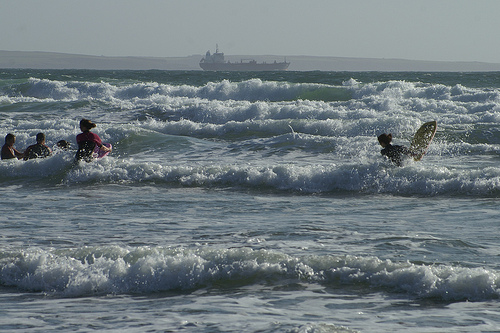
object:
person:
[377, 132, 412, 165]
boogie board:
[406, 121, 436, 162]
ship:
[198, 44, 290, 71]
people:
[0, 133, 26, 159]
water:
[0, 76, 499, 332]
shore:
[0, 48, 500, 79]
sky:
[0, 1, 499, 64]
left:
[0, 3, 27, 329]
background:
[0, 0, 500, 332]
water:
[0, 68, 499, 86]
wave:
[0, 243, 499, 301]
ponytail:
[383, 134, 395, 140]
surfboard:
[96, 142, 113, 159]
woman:
[73, 118, 113, 163]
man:
[54, 140, 70, 147]